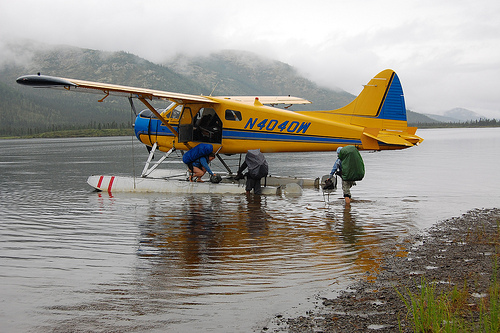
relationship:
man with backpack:
[227, 139, 282, 207] [245, 149, 268, 180]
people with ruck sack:
[188, 152, 217, 182] [180, 139, 213, 165]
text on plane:
[242, 118, 314, 137] [15, 68, 425, 196]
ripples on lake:
[211, 220, 323, 292] [0, 127, 499, 329]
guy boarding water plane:
[326, 146, 357, 206] [16, 68, 425, 195]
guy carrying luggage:
[316, 132, 395, 213] [337, 142, 366, 184]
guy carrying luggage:
[326, 146, 357, 206] [323, 176, 334, 191]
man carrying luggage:
[237, 149, 269, 195] [231, 171, 243, 183]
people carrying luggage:
[176, 142, 223, 182] [210, 170, 222, 185]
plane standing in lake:
[15, 68, 425, 196] [0, 127, 499, 333]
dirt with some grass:
[271, 204, 499, 330] [389, 258, 500, 333]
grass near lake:
[389, 258, 500, 333] [0, 127, 499, 333]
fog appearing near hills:
[0, 0, 356, 95] [1, 37, 499, 141]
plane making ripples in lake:
[15, 69, 423, 197] [0, 127, 499, 333]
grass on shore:
[399, 284, 493, 331] [348, 201, 498, 331]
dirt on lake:
[260, 208, 499, 333] [0, 127, 499, 333]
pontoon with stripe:
[86, 172, 281, 198] [108, 172, 115, 200]